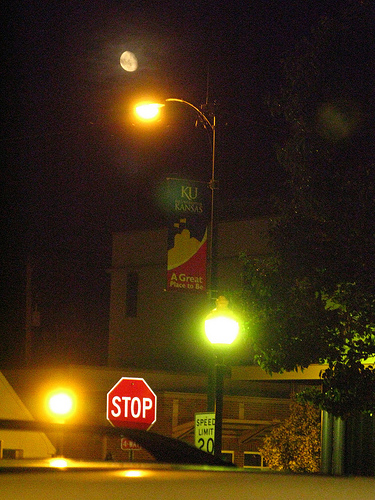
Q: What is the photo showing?
A: It is showing a city.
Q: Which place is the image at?
A: It is at the city.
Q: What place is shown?
A: It is a city.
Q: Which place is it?
A: It is a city.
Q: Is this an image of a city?
A: Yes, it is showing a city.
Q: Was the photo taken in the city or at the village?
A: It was taken at the city.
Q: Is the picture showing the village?
A: No, the picture is showing the city.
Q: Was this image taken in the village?
A: No, the picture was taken in the city.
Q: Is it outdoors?
A: Yes, it is outdoors.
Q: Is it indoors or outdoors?
A: It is outdoors.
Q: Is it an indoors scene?
A: No, it is outdoors.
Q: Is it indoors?
A: No, it is outdoors.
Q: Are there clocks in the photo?
A: No, there are no clocks.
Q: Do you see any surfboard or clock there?
A: No, there are no clocks or surfboards.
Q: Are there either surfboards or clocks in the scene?
A: No, there are no clocks or surfboards.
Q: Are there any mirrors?
A: No, there are no mirrors.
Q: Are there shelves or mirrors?
A: No, there are no mirrors or shelves.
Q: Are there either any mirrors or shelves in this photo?
A: No, there are no mirrors or shelves.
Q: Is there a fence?
A: No, there are no fences.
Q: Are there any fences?
A: No, there are no fences.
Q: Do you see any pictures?
A: No, there are no pictures.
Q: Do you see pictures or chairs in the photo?
A: No, there are no pictures or chairs.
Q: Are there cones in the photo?
A: No, there are no cones.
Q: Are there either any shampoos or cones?
A: No, there are no cones or shampoos.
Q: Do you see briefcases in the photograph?
A: No, there are no briefcases.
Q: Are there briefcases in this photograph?
A: No, there are no briefcases.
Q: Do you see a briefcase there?
A: No, there are no briefcases.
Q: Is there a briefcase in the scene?
A: No, there are no briefcases.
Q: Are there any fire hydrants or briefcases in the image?
A: No, there are no briefcases or fire hydrants.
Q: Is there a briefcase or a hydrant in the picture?
A: No, there are no briefcases or fire hydrants.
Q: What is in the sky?
A: The moon is in the sky.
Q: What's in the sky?
A: The moon is in the sky.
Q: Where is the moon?
A: The moon is in the sky.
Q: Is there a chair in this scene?
A: No, there are no chairs.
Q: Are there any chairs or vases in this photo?
A: No, there are no chairs or vases.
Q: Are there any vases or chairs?
A: No, there are no chairs or vases.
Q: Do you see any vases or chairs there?
A: No, there are no chairs or vases.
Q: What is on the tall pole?
A: The poster is on the pole.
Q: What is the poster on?
A: The poster is on the pole.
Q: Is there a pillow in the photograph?
A: No, there are no pillows.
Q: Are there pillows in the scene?
A: No, there are no pillows.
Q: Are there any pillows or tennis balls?
A: No, there are no pillows or tennis balls.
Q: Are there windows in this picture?
A: Yes, there is a window.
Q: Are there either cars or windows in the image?
A: Yes, there is a window.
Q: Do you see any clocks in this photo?
A: No, there are no clocks.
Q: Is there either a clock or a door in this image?
A: No, there are no clocks or doors.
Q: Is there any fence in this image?
A: No, there are no fences.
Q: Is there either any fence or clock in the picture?
A: No, there are no fences or clocks.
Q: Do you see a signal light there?
A: No, there are no traffic lights.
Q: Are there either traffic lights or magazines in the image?
A: No, there are no traffic lights or magazines.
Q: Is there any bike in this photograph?
A: No, there are no bikes.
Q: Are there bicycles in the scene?
A: No, there are no bicycles.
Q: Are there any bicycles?
A: No, there are no bicycles.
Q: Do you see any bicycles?
A: No, there are no bicycles.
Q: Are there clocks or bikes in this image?
A: No, there are no bikes or clocks.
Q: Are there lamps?
A: Yes, there is a lamp.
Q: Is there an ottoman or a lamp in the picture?
A: Yes, there is a lamp.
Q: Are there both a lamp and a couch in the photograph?
A: No, there is a lamp but no couches.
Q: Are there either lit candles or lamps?
A: Yes, there is a lit lamp.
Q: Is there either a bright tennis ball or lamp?
A: Yes, there is a bright lamp.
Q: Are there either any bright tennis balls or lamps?
A: Yes, there is a bright lamp.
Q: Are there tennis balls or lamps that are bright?
A: Yes, the lamp is bright.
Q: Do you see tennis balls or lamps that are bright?
A: Yes, the lamp is bright.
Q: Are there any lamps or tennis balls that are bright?
A: Yes, the lamp is bright.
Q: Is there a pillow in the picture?
A: No, there are no pillows.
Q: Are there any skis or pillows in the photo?
A: No, there are no pillows or skis.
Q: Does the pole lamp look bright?
A: Yes, the lamp is bright.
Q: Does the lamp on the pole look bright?
A: Yes, the lamp is bright.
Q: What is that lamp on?
A: The lamp is on the pole.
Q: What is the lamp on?
A: The lamp is on the pole.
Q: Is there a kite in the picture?
A: No, there are no kites.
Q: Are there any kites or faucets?
A: No, there are no kites or faucets.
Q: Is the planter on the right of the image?
A: Yes, the planter is on the right of the image.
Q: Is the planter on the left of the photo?
A: No, the planter is on the right of the image.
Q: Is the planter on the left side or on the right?
A: The planter is on the right of the image.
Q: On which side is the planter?
A: The planter is on the right of the image.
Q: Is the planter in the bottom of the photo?
A: Yes, the planter is in the bottom of the image.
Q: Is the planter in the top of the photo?
A: No, the planter is in the bottom of the image.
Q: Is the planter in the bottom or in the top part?
A: The planter is in the bottom of the image.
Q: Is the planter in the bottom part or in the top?
A: The planter is in the bottom of the image.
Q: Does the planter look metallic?
A: Yes, the planter is metallic.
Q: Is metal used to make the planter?
A: Yes, the planter is made of metal.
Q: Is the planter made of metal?
A: Yes, the planter is made of metal.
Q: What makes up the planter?
A: The planter is made of metal.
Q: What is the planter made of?
A: The planter is made of metal.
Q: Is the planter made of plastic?
A: No, the planter is made of metal.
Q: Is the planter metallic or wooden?
A: The planter is metallic.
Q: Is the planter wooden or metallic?
A: The planter is metallic.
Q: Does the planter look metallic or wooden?
A: The planter is metallic.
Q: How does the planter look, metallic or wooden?
A: The planter is metallic.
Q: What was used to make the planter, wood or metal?
A: The planter is made of metal.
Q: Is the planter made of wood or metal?
A: The planter is made of metal.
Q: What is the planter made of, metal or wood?
A: The planter is made of metal.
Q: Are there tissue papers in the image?
A: No, there are no tissue papers.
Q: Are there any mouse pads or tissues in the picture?
A: No, there are no tissues or mouse pads.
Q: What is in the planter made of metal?
A: The plant is in the planter.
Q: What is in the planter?
A: The plant is in the planter.